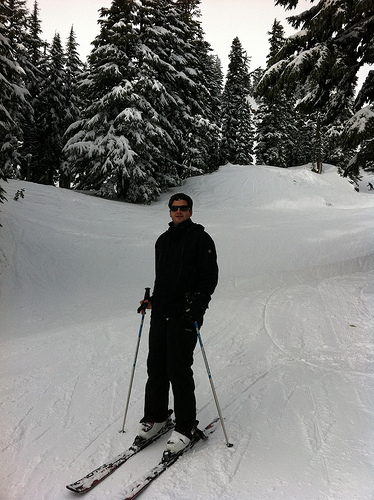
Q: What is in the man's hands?
A: Ski poles.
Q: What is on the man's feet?
A: Skis.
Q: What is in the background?
A: Snow covered trees.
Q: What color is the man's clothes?
A: Black.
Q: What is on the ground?
A: Snow.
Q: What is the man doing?
A: Skiing.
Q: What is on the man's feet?
A: Black skis.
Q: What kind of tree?
A: Evergreen.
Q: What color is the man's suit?
A: Black.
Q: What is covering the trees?
A: Snow.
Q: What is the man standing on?
A: Skis.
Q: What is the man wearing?
A: Black snowsuit.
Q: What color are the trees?
A: White and green.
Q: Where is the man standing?
A: On snow.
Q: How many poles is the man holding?
A: Two.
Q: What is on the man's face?
A: Sunglasses.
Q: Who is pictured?
A: A man on snow skis.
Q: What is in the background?
A: Snow covered trees.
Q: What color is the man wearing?
A: Black.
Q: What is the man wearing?
A: Sunglasses.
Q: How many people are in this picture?
A: One man.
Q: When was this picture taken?
A: Maybe morning.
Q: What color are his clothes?
A: Black.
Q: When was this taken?
A: During the day.